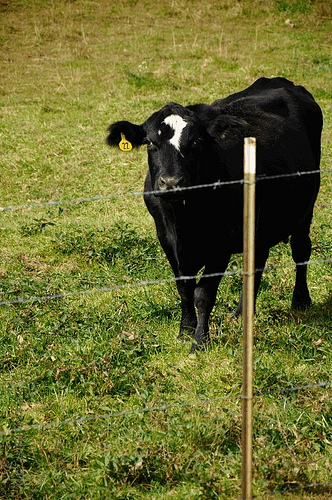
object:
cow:
[104, 73, 325, 361]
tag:
[118, 132, 132, 153]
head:
[104, 98, 252, 202]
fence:
[0, 167, 332, 500]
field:
[0, 0, 332, 500]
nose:
[152, 174, 187, 199]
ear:
[102, 118, 143, 152]